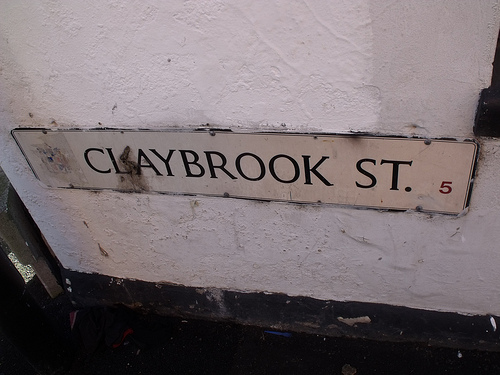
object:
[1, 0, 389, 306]
stucco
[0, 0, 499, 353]
wall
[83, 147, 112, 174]
letter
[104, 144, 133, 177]
letter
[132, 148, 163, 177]
letter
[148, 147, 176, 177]
letter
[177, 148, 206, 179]
letter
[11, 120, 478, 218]
sign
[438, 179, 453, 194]
number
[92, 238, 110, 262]
dirt speck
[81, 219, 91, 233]
dirt speck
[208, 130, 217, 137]
screw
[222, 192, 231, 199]
screw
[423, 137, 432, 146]
screw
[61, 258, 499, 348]
strip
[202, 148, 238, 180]
letter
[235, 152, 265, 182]
letter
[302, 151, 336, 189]
letter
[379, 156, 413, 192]
letter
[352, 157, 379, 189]
letter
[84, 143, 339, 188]
word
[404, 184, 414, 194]
point